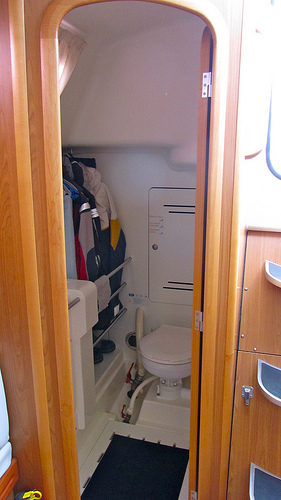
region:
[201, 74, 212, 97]
Silver hinge on door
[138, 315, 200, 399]
White toilet in bathroom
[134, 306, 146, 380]
Water pipe beside toilet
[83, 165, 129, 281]
Jacket hanging in bathroom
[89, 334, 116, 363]
Boots on shelf in bathroom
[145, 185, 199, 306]
Door behind toilet in bathroom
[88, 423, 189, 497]
Black mat on floor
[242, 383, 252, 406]
Metal handle on door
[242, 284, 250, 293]
Silver rivet on door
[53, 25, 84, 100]
White curtain in bathroom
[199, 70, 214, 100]
Hinge on door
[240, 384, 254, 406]
Latch on cabinet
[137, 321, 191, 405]
Toilet is white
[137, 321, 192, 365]
toilet seat is closed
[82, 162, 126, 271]
Jacket is blue, yellow and white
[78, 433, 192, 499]
Mat on floor is black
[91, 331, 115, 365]
Boots in the clothes area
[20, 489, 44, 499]
Yellow pull on object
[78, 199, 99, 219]
Silver stripes on jacket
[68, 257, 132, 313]
Handrails in bathroom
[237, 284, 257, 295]
button on the door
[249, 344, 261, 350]
button on the door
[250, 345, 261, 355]
button on the door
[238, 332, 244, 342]
button on the door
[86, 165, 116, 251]
clothing hanging on rack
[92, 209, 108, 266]
clothing hanging on rack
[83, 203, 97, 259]
clothing hanging on rack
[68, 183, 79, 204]
clothing hanging on rack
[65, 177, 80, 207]
clothing hanging on rack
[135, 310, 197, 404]
a white toilet with a white lid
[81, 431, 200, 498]
a black bathroom rug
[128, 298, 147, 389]
a white pipe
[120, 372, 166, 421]
a white pipe with a red valve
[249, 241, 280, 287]
a storage shelf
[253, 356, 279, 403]
a storage shelf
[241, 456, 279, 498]
a storage shelf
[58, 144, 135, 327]
clothes hanging up in a closet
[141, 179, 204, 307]
a white access panel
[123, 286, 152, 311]
a white sticker with blue lettering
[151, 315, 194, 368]
white lid of small toliet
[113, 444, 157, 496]
dark black rug on bathroom floor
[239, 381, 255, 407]
silver door handle on right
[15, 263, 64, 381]
light brown wooden door frame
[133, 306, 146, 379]
drain hose in back of toliet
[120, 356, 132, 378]
red shut off valve on toliet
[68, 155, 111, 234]
clothing hung in shower area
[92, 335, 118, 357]
big boots in shower area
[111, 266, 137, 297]
silver metal bars besides toliet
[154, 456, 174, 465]
the rug is black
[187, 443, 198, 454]
the door is wooden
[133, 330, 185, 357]
lid of the toilet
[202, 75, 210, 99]
railing of the door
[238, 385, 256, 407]
knob on the door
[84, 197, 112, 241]
the clothes are hanging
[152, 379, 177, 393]
bottom of the toilet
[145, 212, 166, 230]
label on the wall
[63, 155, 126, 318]
sleeves of hanging jackets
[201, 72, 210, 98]
three screws of metal hinge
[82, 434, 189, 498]
dark blue bathroom rug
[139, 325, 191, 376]
toilet bowl with closed lid